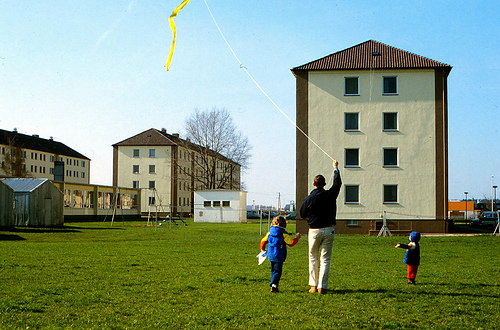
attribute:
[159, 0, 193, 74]
kite — yellow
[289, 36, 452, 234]
building — white, brown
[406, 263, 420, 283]
pants — red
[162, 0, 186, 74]
kite — yellow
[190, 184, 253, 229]
shed — white, small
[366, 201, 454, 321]
boy — young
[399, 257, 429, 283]
pants — red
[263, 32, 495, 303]
building — short, white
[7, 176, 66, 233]
shed — silver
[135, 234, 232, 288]
grass — white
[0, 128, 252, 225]
buildings — grassy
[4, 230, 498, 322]
area — green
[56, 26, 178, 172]
clouds — white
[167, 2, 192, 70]
kite tail — yellow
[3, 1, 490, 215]
sky — blue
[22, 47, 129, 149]
clouds — white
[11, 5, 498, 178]
sky — blue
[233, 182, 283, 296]
child — young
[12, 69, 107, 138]
clouds — white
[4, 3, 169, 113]
sky — blue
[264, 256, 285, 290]
pants — blue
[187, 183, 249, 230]
shack — small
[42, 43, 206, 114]
clouds — white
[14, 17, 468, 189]
sky — blue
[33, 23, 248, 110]
clouds — white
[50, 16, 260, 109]
clouds — white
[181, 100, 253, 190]
tree — bare